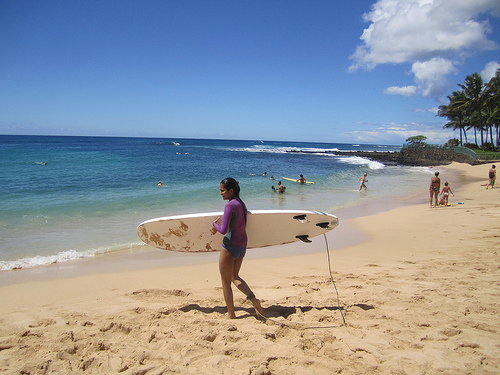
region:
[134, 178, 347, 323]
Woman with a surfboard standing in the sand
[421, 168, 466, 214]
A woman and child standing on the beach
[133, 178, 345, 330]
A woman standing on the sand with surfboard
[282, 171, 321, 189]
A woman with a surfboard in the water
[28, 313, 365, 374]
Small sand dunes on a beach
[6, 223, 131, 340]
Waves rolling up to the shore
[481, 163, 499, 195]
A woman walking on the beach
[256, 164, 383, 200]
People in the water at the beach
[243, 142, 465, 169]
Distant waves crashing against the beach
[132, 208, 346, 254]
A sand stained surfboard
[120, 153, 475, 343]
people on the beach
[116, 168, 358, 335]
girl carrying surfboard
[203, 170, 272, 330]
girl wearing purple wet suit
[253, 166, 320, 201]
people in the water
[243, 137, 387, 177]
waves crashing against shore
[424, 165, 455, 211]
two people standing in sand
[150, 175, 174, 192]
person swimming in the ocean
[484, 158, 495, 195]
person walking on the sand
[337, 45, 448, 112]
white clouds in the sky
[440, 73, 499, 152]
tall palm trees on shore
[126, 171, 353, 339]
girl carrying a surfboard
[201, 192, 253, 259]
girl is wearing a purple bathing suit top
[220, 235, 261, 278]
girl is wearing blue bikini bottoms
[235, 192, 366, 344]
girl has a lanyard connected to her surfboard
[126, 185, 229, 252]
sand is stuck to the bottom of the surfboard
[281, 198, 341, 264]
three black objects sticking out of the bottom of board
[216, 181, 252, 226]
girl has dark colored hair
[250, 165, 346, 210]
few swimmers in the water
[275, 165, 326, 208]
person in background has sufboard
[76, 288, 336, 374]
many footprints in the sand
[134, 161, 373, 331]
woman carrying a surfboard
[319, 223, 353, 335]
string hanging down from the board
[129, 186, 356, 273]
long white surfboard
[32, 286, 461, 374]
footprints in the sand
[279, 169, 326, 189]
person on a surfboard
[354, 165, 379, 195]
person walking in the water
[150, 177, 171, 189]
person in the water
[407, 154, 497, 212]
three people walking on the beach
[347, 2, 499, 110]
puffy white clouds in the sky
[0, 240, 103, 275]
wave rolling into shore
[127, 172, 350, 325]
a woman carrying a white surfboard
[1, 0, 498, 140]
a clear blue sky with a few clouds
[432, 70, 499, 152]
a row of palm trees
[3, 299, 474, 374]
a bunch of footprints in the sand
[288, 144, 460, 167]
a rock jetty spanning out into the ocean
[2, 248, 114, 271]
a small wave lapping up on the shore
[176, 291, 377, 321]
a shadow of the girl and surfboard cast on the sand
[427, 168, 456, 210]
a mother and child standing on the beach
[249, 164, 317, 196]
people playing in the ocean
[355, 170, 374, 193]
a person running out of the water